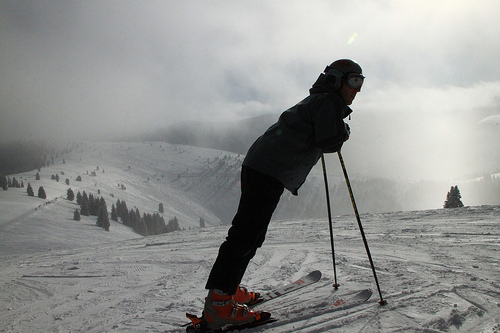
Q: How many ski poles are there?
A: Two.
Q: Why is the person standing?
A: Getting ready to ski.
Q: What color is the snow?
A: White.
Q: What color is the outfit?
A: Black.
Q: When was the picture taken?
A: Winter time.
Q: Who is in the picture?
A: A skier.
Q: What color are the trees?
A: Green.